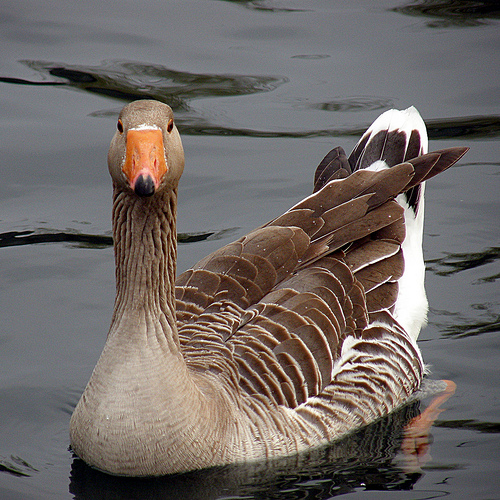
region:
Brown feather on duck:
[320, 190, 380, 234]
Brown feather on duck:
[346, 238, 397, 276]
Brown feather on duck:
[358, 251, 405, 294]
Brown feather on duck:
[362, 280, 399, 307]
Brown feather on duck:
[315, 255, 353, 296]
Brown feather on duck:
[278, 265, 345, 307]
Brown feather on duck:
[311, 284, 348, 331]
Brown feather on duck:
[256, 288, 293, 305]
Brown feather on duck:
[256, 318, 290, 342]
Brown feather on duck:
[291, 320, 333, 387]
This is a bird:
[38, 92, 469, 492]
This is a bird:
[37, 71, 472, 496]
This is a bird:
[49, 75, 464, 490]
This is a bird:
[55, 93, 480, 493]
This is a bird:
[53, 71, 480, 494]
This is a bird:
[53, 93, 486, 498]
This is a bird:
[65, 75, 469, 491]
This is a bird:
[68, 94, 478, 496]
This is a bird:
[63, 92, 467, 479]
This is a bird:
[71, 88, 462, 490]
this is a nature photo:
[33, 40, 423, 440]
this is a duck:
[64, 133, 376, 408]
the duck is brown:
[73, 136, 411, 476]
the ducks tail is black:
[339, 122, 413, 182]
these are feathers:
[216, 301, 388, 443]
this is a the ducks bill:
[105, 124, 190, 212]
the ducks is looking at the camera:
[94, 111, 229, 323]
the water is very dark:
[23, 149, 115, 358]